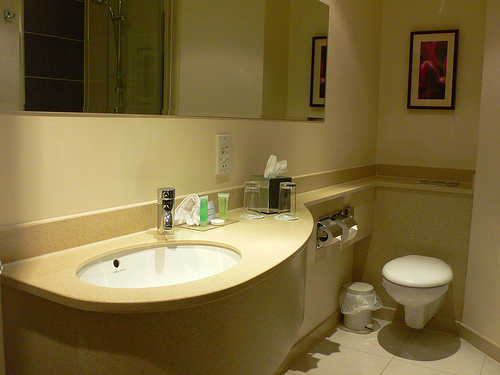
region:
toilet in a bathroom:
[376, 244, 460, 336]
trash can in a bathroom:
[331, 276, 390, 346]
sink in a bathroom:
[76, 240, 255, 290]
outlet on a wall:
[211, 128, 250, 190]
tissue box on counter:
[246, 151, 305, 225]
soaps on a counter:
[192, 192, 238, 230]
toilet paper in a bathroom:
[312, 197, 367, 257]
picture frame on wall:
[393, 18, 463, 123]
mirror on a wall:
[6, 6, 344, 134]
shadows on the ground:
[267, 320, 356, 368]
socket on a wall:
[216, 132, 229, 176]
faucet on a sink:
[156, 188, 175, 233]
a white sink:
[77, 244, 243, 283]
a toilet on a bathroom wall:
[382, 253, 453, 330]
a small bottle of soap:
[217, 189, 228, 218]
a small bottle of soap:
[198, 196, 208, 226]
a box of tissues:
[249, 154, 293, 216]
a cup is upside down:
[277, 180, 295, 222]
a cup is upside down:
[242, 179, 260, 219]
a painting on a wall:
[409, 28, 456, 111]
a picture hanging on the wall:
[400, 25, 462, 112]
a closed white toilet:
[379, 248, 454, 335]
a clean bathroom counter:
[8, 184, 320, 373]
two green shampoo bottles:
[194, 193, 234, 229]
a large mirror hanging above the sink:
[3, 5, 336, 130]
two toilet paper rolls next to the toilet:
[312, 210, 366, 253]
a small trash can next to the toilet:
[334, 276, 385, 335]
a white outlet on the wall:
[211, 131, 236, 178]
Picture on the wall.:
[394, 18, 465, 123]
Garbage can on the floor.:
[332, 274, 379, 339]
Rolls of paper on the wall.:
[318, 201, 358, 256]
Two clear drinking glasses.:
[237, 177, 303, 223]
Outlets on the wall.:
[212, 115, 241, 183]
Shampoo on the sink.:
[193, 193, 208, 231]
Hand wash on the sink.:
[213, 188, 230, 223]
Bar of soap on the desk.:
[208, 213, 235, 231]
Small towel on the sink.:
[173, 187, 210, 234]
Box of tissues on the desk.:
[245, 144, 290, 214]